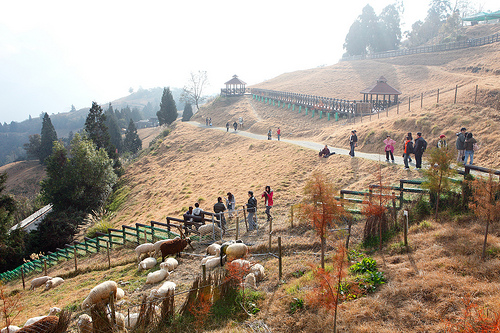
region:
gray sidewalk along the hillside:
[186, 116, 498, 181]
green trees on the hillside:
[3, 100, 141, 266]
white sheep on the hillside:
[1, 220, 268, 330]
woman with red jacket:
[261, 183, 276, 215]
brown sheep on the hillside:
[158, 235, 190, 261]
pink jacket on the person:
[379, 135, 397, 153]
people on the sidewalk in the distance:
[202, 113, 284, 141]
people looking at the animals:
[183, 183, 275, 230]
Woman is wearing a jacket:
[261, 188, 273, 209]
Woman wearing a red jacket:
[257, 188, 279, 208]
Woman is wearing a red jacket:
[261, 187, 275, 206]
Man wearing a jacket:
[242, 194, 257, 216]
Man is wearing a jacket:
[246, 195, 263, 217]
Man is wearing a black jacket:
[245, 191, 259, 214]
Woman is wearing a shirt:
[382, 135, 399, 150]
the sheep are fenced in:
[12, 207, 274, 332]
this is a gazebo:
[357, 66, 411, 116]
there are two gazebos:
[205, 60, 415, 114]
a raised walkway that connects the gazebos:
[227, 73, 368, 129]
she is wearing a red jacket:
[255, 168, 287, 230]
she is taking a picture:
[256, 176, 283, 228]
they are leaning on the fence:
[177, 183, 209, 240]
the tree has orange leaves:
[287, 151, 353, 295]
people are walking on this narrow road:
[184, 105, 451, 186]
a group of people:
[164, 168, 321, 245]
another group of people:
[335, 122, 446, 156]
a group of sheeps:
[23, 238, 249, 331]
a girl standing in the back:
[245, 173, 292, 233]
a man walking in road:
[323, 116, 376, 173]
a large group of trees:
[18, 108, 153, 216]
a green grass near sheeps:
[336, 236, 396, 301]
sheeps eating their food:
[34, 235, 261, 328]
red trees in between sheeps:
[295, 240, 348, 322]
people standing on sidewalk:
[185, 91, 481, 182]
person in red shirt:
[262, 181, 277, 216]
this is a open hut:
[351, 71, 403, 116]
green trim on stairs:
[0, 207, 190, 282]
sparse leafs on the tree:
[282, 147, 360, 309]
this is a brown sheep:
[149, 234, 210, 268]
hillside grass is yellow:
[160, 131, 268, 193]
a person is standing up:
[464, 127, 478, 162]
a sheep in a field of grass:
[28, 275, 51, 288]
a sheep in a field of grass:
[75, 273, 122, 303]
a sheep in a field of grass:
[133, 255, 155, 273]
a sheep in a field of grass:
[196, 255, 223, 267]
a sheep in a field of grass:
[228, 257, 250, 269]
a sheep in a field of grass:
[221, 240, 248, 256]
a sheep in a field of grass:
[133, 240, 159, 252]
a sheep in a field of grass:
[157, 239, 193, 256]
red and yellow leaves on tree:
[286, 162, 351, 269]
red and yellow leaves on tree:
[281, 158, 347, 279]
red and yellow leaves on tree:
[284, 168, 354, 277]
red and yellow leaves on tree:
[280, 163, 362, 280]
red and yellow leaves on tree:
[286, 152, 361, 276]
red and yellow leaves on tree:
[284, 154, 356, 269]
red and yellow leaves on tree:
[279, 155, 349, 265]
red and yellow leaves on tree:
[284, 155, 354, 260]